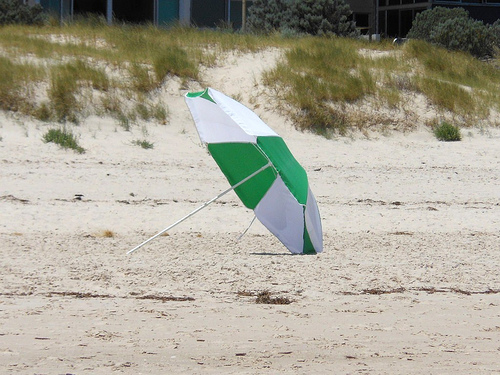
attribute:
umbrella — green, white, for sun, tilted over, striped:
[185, 87, 324, 254]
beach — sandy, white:
[2, 141, 498, 373]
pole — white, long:
[119, 161, 270, 262]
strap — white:
[236, 215, 255, 245]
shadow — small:
[253, 251, 314, 256]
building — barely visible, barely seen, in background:
[3, 1, 499, 40]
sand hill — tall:
[1, 23, 500, 145]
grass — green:
[1, 13, 219, 124]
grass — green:
[223, 23, 290, 53]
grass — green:
[270, 34, 499, 138]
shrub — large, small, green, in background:
[403, 7, 468, 41]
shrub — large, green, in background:
[432, 18, 499, 54]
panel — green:
[209, 142, 276, 207]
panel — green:
[255, 136, 309, 205]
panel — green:
[186, 90, 216, 103]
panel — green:
[302, 207, 317, 255]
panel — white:
[212, 90, 278, 137]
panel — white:
[186, 97, 255, 144]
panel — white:
[255, 175, 305, 252]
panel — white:
[304, 179, 324, 255]